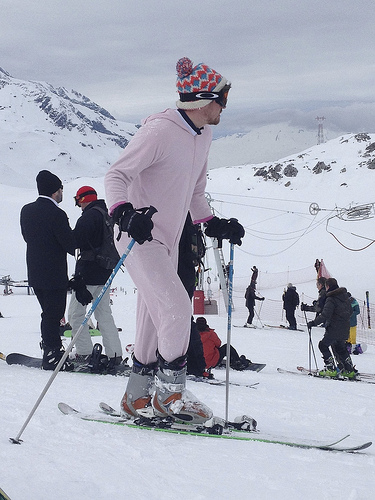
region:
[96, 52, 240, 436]
man in pink sweat suite in front of picture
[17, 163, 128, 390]
man in black hat talking to man in red hat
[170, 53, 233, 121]
multi colored hat on head of skier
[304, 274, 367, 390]
man with black jacket and green ski boots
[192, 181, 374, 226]
metal wires for ski lift above skiers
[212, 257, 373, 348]
fence in back of picture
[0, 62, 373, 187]
mountains in background of picture above skiers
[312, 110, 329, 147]
radio tower behind the mountain in background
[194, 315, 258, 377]
person in red jacket sitting on the snow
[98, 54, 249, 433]
black goggles and black gloves on skier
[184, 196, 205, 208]
Big ski suit on top of thw skis'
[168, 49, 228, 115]
man has colorful hat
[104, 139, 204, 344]
man has pink bodysuit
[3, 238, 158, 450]
blue and silver ski poles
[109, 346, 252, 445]
grey and orange boots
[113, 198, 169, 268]
man has black gloves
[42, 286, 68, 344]
man has black pants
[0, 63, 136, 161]
large grey and white mountain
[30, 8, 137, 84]
sky is grey and cold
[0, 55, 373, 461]
many people on the snow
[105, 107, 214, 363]
man wearing a one-piece light pink outfit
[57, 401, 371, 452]
snow on man's green skis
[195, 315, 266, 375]
person seated on the snow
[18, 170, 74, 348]
man dressed in a formal black suit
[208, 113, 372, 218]
metal structure on a hilltop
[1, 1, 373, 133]
dark grey clouds in the distance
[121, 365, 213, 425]
snow on man's ski boots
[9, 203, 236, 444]
man holding blue and white ski poles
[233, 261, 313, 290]
person standing near distant fence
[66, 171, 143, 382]
this is a person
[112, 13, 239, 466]
this is a person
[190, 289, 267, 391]
this is a person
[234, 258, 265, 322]
this is a person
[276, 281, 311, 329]
this is a person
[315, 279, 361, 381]
this is a person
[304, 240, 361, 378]
this is a person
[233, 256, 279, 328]
this is a person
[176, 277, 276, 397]
this is a person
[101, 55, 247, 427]
man in pink on skis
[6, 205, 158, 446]
long metal blue pole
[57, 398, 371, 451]
long thin white ski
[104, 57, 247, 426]
man is wearing a light pink snow suit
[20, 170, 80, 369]
man is wearing a black ski cap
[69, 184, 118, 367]
man is wearing white pants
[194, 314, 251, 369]
person in the red jacket is sitting down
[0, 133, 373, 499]
ground is white and snowy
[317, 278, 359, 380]
man is wearing green ski boots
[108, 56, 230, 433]
man is wearing a pink and blue cap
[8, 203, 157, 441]
ski pole is blue and white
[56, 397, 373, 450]
skis are green and white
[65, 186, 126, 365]
man is wearing a red ski cap